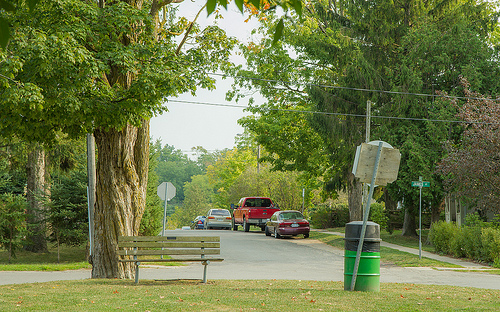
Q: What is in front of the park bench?
A: Patch of grass.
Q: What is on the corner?
A: Bunch of trees.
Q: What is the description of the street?
A: T Shaped.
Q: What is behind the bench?
A: Trunk of tree.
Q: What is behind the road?
A: Tall tree.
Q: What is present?
A: Cars.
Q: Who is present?
A: Nobody.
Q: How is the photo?
A: Clear.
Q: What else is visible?
A: Grass.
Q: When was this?
A: Daytime.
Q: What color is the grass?
A: Green.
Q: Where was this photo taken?
A: A residential park.